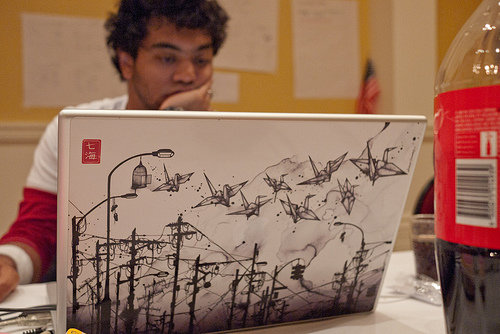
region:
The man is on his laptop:
[11, 9, 411, 332]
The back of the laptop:
[41, 96, 416, 330]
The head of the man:
[103, 4, 228, 109]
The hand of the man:
[158, 77, 218, 114]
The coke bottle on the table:
[428, 7, 498, 332]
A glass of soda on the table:
[407, 205, 445, 287]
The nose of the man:
[171, 57, 201, 87]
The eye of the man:
[148, 44, 178, 69]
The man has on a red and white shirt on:
[0, 98, 156, 278]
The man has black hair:
[86, 1, 240, 84]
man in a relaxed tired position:
[80, 5, 254, 127]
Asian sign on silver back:
[65, 125, 121, 169]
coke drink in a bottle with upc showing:
[410, 21, 497, 273]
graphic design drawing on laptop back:
[113, 130, 413, 287]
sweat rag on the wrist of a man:
[0, 226, 57, 277]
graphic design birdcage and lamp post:
[95, 147, 185, 195]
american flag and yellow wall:
[336, 38, 398, 116]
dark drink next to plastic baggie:
[403, 198, 441, 305]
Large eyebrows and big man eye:
[147, 30, 186, 70]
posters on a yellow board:
[212, 0, 375, 104]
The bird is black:
[152, 154, 191, 196]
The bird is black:
[193, 168, 243, 208]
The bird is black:
[227, 185, 272, 222]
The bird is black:
[258, 168, 293, 201]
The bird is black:
[276, 189, 323, 226]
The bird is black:
[332, 175, 359, 216]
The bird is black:
[298, 143, 346, 189]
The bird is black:
[346, 130, 408, 188]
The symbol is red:
[73, 125, 107, 173]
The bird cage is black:
[124, 153, 154, 195]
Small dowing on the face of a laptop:
[354, 137, 402, 189]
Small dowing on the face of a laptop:
[295, 147, 333, 189]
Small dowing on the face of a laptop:
[333, 182, 358, 214]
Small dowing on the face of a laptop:
[275, 192, 320, 220]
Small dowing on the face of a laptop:
[260, 158, 296, 200]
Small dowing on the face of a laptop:
[238, 190, 283, 235]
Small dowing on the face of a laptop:
[196, 168, 236, 210]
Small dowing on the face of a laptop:
[158, 164, 187, 211]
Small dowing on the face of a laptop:
[101, 155, 167, 326]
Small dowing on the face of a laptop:
[161, 210, 264, 306]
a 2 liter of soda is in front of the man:
[417, 23, 499, 328]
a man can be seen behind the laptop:
[4, 5, 352, 305]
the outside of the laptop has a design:
[60, 115, 380, 325]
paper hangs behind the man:
[18, 0, 456, 125]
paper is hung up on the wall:
[14, 3, 366, 118]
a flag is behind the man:
[357, 43, 387, 120]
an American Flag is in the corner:
[347, 53, 395, 120]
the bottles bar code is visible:
[446, 145, 499, 235]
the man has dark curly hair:
[105, 0, 224, 72]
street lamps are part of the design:
[76, 140, 371, 327]